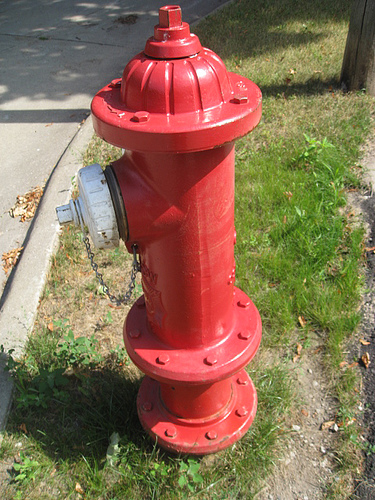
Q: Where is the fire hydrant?
A: Curbside.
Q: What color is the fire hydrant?
A: Red.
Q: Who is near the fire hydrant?
A: No one.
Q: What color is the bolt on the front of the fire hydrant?
A: Silver.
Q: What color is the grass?
A: Green.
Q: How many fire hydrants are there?
A: One.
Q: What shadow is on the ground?
A: Tree.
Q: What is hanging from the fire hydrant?
A: Chain.